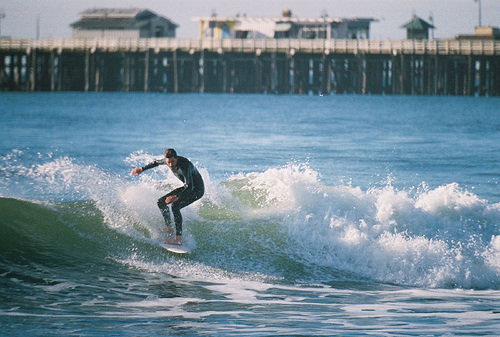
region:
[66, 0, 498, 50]
buildings on the boardwalk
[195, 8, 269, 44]
a yellow building on boardwalk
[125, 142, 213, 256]
man in wet suit surfing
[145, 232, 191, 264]
a white surfboard crashing waves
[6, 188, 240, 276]
a great wave the surfer is riding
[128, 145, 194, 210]
dark haired man surfing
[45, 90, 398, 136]
light blue clean ocean water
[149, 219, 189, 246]
the surfers bare feet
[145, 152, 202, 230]
wet suit the surfer is wearing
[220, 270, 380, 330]
foam in the water from the waves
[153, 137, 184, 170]
head of a person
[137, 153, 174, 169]
arm of a person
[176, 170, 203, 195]
arm of a person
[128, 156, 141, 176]
hand of a person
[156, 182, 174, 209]
hand of a person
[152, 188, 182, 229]
leg of a person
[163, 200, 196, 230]
leg of a person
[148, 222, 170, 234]
feet of a person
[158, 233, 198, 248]
feet of a person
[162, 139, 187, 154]
hair of a person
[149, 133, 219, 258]
Man surfing on the water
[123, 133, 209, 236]
man wearing a black wet suit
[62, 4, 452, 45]
Houses near the pier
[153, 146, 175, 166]
man with brown hair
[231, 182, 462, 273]
waves crashing in the water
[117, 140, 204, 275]
man on a white surfboard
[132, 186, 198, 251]
man on a white surfboard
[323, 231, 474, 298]
waves crashing in the water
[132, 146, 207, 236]
surfer in black wet suit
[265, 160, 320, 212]
white and gray ocean waves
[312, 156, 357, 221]
white and gray ocean waves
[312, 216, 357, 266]
white and gray ocean waves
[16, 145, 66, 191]
white and gray ocean waves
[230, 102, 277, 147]
white and gray ocean waves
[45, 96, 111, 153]
white and gray ocean waves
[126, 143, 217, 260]
surfer on the water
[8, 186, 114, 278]
wave in the ocean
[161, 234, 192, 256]
surfboard in the water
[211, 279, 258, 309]
foam on the water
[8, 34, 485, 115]
pier besides the water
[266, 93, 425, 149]
water of an ocean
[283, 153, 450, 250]
water splashing in the ocean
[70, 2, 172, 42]
building on a pier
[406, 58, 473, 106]
wood planks of a pier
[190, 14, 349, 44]
fence of a pier